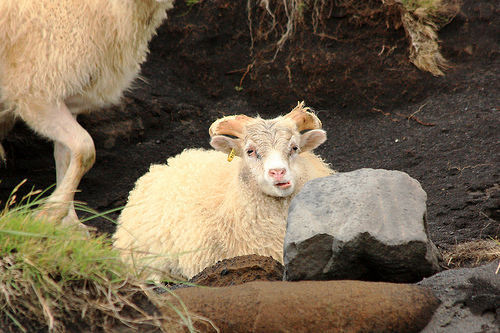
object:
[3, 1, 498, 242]
dirt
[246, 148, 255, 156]
eye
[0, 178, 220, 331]
grass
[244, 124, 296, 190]
face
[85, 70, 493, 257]
soil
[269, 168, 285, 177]
nose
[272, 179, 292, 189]
mouth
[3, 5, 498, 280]
ground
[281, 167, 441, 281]
rock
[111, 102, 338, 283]
goat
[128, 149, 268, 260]
body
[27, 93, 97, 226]
leg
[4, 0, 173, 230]
goat